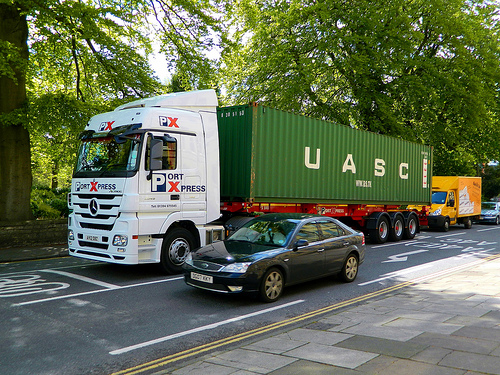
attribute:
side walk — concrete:
[224, 247, 492, 374]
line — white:
[4, 217, 496, 373]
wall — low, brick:
[1, 220, 67, 262]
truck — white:
[64, 89, 215, 251]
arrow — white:
[384, 247, 419, 268]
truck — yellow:
[403, 174, 483, 231]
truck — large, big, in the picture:
[67, 89, 432, 273]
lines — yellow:
[107, 247, 498, 372]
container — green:
[199, 97, 436, 216]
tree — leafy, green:
[248, 2, 488, 154]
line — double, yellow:
[183, 324, 233, 343]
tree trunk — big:
[5, 122, 42, 215]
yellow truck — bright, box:
[404, 175, 481, 230]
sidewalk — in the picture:
[157, 252, 499, 370]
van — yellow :
[420, 173, 480, 231]